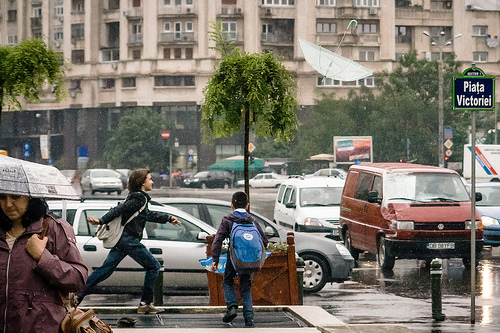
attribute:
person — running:
[99, 162, 185, 294]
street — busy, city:
[115, 271, 492, 330]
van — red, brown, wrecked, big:
[349, 166, 490, 261]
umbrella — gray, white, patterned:
[7, 162, 96, 209]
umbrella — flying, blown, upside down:
[290, 37, 373, 94]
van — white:
[258, 173, 333, 234]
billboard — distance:
[312, 124, 390, 168]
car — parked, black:
[186, 175, 246, 192]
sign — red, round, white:
[154, 125, 180, 144]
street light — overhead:
[423, 29, 458, 154]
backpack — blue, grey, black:
[230, 223, 262, 275]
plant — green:
[268, 238, 303, 257]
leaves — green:
[226, 79, 273, 97]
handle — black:
[147, 240, 177, 259]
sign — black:
[438, 72, 499, 120]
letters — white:
[465, 82, 484, 99]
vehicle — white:
[276, 175, 320, 227]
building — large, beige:
[33, 19, 350, 177]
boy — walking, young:
[185, 189, 283, 318]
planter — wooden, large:
[247, 256, 307, 309]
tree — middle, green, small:
[204, 58, 290, 222]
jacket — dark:
[127, 197, 150, 233]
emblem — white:
[241, 230, 254, 244]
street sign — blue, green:
[445, 68, 499, 115]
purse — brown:
[52, 301, 119, 329]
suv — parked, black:
[181, 163, 247, 198]